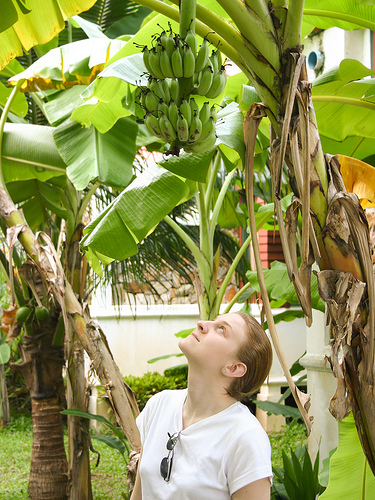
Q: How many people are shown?
A: 1.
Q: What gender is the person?
A: Female.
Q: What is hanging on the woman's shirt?
A: Sunglasses.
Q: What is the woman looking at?
A: Bananas.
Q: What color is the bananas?
A: Green.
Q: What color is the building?
A: White.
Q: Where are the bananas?
A: Above the woman.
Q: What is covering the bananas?
A: Leaves.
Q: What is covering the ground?
A: Grass.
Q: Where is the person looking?
A: Up.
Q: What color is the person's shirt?
A: White.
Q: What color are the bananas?
A: Green.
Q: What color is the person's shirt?
A: White.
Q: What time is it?
A: Afternoon.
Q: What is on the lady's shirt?
A: Glasses.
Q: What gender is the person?
A: Female.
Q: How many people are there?
A: One.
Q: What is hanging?
A: Bananas.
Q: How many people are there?
A: One.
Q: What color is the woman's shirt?
A: White.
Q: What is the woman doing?
A: Looking up.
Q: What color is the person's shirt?
A: White.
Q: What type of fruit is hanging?
A: Banana.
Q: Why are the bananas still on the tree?
A: Not ripe yet.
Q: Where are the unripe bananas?
A: Above person.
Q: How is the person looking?
A: Up.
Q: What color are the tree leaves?
A: Green.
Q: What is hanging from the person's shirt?
A: Sunglasses.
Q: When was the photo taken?
A: During day.